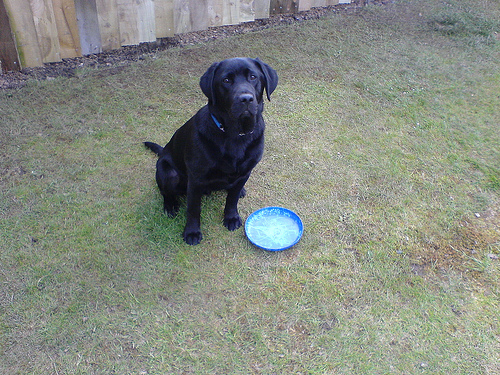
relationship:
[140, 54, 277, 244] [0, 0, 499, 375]
dog on top of fluffy grass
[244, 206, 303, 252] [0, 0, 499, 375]
frisbee on top of fluffy grass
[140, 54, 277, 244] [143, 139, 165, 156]
dog has tail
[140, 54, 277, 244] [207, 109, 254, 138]
dog wearing collar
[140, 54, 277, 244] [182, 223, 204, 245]
dog has paw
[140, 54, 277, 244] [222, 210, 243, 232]
dog has paw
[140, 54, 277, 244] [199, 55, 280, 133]
dog has head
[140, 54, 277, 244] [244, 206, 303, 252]
dog in front of frisbee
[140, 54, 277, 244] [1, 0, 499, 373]
dog inside of yard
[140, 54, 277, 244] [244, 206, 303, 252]
dog playing with frisbee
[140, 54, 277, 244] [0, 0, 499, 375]
dog sitting on fluffy grass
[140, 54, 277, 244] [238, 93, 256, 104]
dog has nose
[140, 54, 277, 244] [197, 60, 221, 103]
dog has ear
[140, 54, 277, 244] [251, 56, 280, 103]
dog has ear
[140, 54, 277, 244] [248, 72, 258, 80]
dog has eye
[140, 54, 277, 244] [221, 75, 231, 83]
dog has eye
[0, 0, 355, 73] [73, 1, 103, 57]
fence has wood plank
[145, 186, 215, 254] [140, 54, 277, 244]
fluffy grass underneath dog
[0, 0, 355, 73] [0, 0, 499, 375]
fence next to fluffy grass